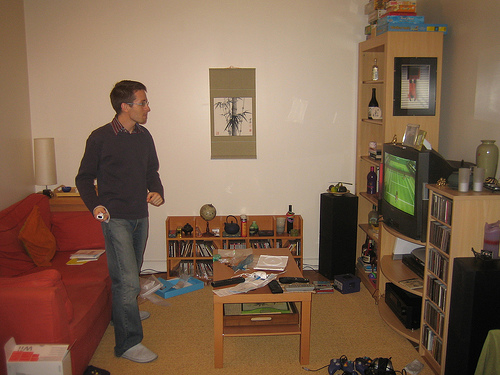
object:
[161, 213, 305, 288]
organizer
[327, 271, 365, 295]
gaming system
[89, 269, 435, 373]
floor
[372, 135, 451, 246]
tv screen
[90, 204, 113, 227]
controller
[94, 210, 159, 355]
jeans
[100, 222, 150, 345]
blue jeans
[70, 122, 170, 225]
sweater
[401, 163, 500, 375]
wood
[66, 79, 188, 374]
man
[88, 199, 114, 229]
wii controller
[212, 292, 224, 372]
leg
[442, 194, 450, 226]
cd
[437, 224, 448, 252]
cd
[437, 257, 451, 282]
cd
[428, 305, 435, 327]
cd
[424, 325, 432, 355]
cd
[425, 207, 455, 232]
shelf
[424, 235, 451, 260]
shelf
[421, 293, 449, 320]
shelf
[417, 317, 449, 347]
shelf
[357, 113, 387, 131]
shelf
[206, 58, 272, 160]
picture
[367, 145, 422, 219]
giraffe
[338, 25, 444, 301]
bookcase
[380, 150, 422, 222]
screen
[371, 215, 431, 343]
tv stand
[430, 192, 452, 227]
cds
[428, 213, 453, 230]
shelf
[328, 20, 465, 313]
shelf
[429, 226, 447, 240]
cd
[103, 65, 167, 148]
head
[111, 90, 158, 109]
eyeglasses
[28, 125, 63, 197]
lamp shade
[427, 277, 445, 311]
cd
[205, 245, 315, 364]
table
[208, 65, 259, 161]
picture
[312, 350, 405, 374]
game controls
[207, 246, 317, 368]
coffee table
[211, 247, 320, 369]
wood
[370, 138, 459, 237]
tv set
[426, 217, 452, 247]
cd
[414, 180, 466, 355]
shelf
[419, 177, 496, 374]
organizer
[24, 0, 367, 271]
wall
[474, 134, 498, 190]
vase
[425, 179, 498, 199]
shelf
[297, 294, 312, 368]
leg